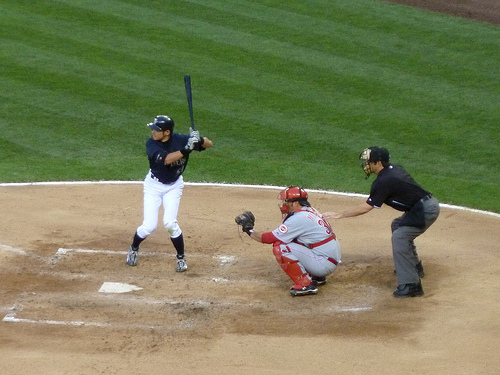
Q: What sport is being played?
A: Baseball.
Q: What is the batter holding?
A: A baseball bat.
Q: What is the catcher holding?
A: A catcher's mitt.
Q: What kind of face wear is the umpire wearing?
A: A mask.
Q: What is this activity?
A: Baseball.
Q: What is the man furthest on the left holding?
A: Baseball bat.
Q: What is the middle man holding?
A: Baseball mitt.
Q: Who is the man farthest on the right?
A: Umpire.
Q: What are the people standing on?
A: Dirt.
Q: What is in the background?
A: Grass.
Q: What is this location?
A: Baseball diamond.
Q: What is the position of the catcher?
A: Crouched.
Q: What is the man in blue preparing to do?
A: Hit the ball.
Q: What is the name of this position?
A: This is the umpire.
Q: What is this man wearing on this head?
A: This man is wearing a helmet.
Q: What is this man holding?
A: This man is holding a baseball bat.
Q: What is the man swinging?
A: The man is swinging a bat.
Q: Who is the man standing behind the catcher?
A: This man is the umpire.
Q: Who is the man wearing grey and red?
A: This man is the catcher.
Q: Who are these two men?
A: The umpire and the catcher.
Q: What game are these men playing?
A: They are playing baseball.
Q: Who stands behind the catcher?
A: Is a umpire.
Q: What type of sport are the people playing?
A: Baseball.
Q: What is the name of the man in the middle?
A: Catcher.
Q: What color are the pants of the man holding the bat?
A: White.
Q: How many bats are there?
A: One.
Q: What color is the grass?
A: Green.